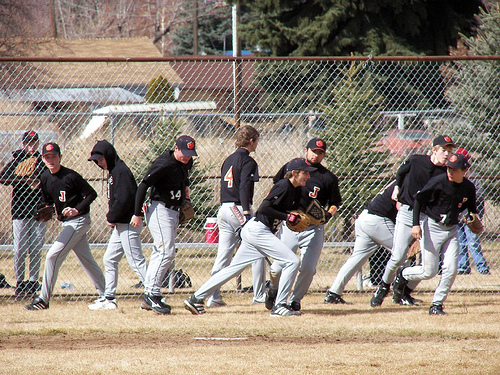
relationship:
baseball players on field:
[7, 130, 495, 306] [205, 344, 302, 363]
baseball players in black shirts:
[7, 130, 495, 306] [406, 161, 458, 202]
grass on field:
[76, 351, 139, 364] [205, 344, 302, 363]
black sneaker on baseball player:
[141, 294, 172, 326] [137, 134, 196, 305]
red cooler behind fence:
[203, 216, 223, 248] [302, 80, 348, 88]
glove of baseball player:
[282, 217, 324, 231] [137, 134, 196, 305]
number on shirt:
[155, 188, 181, 208] [141, 161, 202, 218]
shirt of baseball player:
[141, 161, 202, 218] [137, 134, 196, 305]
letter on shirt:
[59, 191, 76, 210] [41, 179, 88, 220]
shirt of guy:
[41, 179, 88, 220] [38, 139, 94, 300]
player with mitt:
[260, 155, 295, 297] [297, 196, 311, 231]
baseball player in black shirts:
[137, 134, 196, 305] [406, 161, 458, 202]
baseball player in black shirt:
[137, 134, 196, 305] [221, 160, 257, 203]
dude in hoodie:
[87, 125, 142, 301] [96, 139, 131, 218]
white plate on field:
[184, 330, 257, 346] [205, 344, 302, 363]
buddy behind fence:
[10, 135, 44, 305] [302, 80, 348, 88]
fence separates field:
[302, 80, 348, 88] [205, 344, 302, 363]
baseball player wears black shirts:
[137, 134, 196, 305] [406, 161, 458, 202]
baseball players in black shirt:
[7, 130, 495, 306] [221, 160, 257, 203]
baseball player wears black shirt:
[137, 134, 196, 305] [221, 160, 257, 203]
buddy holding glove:
[10, 135, 44, 305] [282, 217, 324, 231]